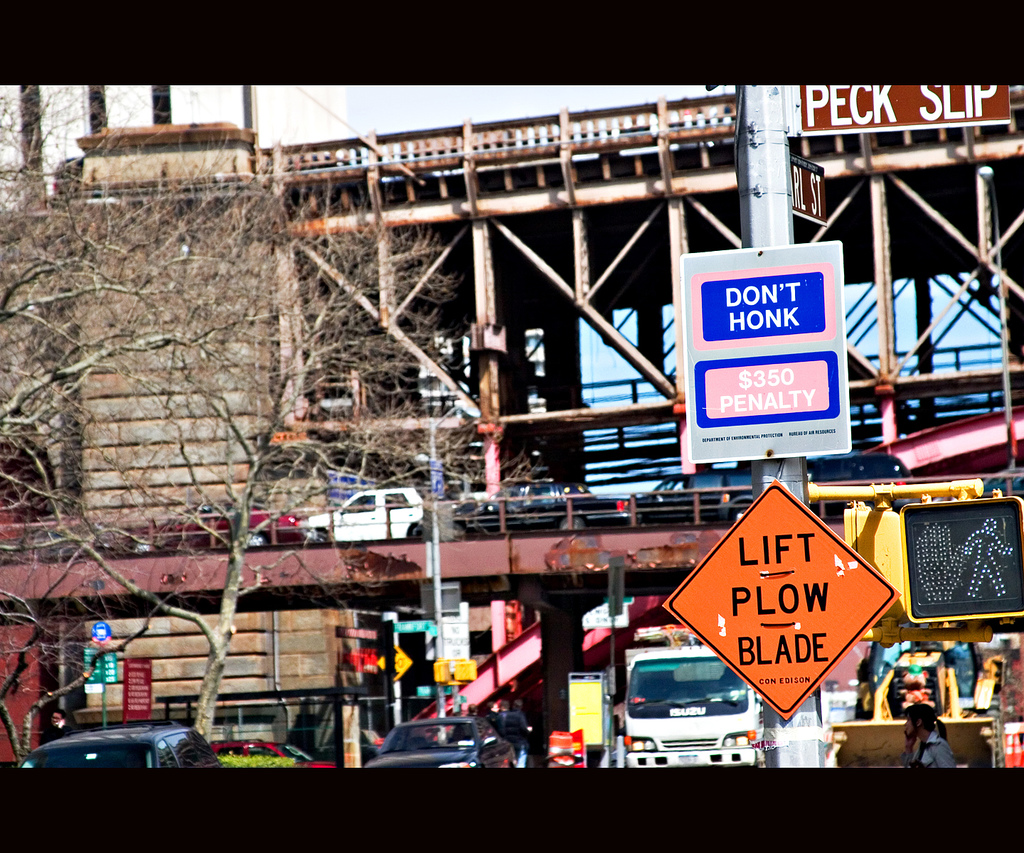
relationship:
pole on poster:
[700, 102, 838, 232] [673, 248, 881, 461]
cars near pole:
[310, 437, 637, 545] [700, 102, 838, 232]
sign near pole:
[651, 494, 890, 729] [700, 102, 838, 232]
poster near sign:
[673, 248, 881, 461] [651, 494, 890, 729]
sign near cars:
[651, 494, 890, 729] [310, 437, 637, 545]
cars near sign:
[310, 437, 637, 545] [651, 494, 890, 729]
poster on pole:
[673, 248, 881, 461] [700, 102, 838, 232]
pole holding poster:
[700, 102, 838, 232] [673, 248, 881, 461]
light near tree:
[424, 649, 490, 697] [64, 179, 412, 384]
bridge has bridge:
[294, 134, 627, 178] [0, 84, 1022, 240]